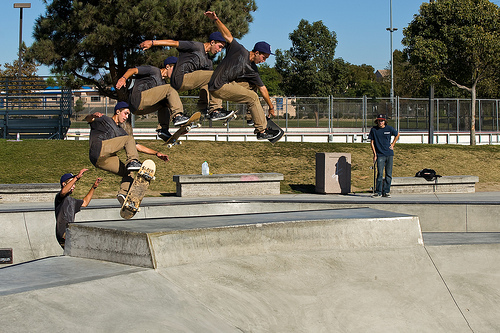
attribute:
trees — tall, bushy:
[17, 0, 273, 118]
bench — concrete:
[373, 166, 475, 198]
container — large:
[201, 158, 209, 175]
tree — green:
[292, 20, 354, 124]